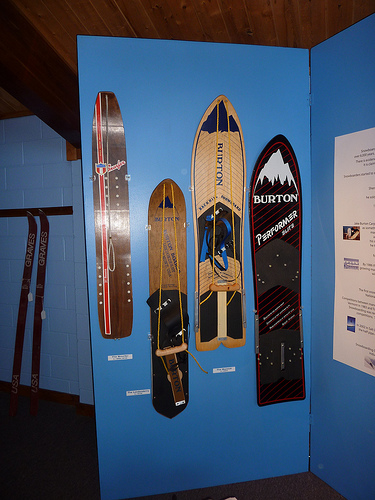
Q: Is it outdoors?
A: Yes, it is outdoors.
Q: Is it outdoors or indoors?
A: It is outdoors.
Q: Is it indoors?
A: No, it is outdoors.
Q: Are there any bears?
A: No, there are no bears.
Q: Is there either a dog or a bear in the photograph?
A: No, there are no bears or dogs.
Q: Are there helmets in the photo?
A: No, there are no helmets.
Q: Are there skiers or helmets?
A: No, there are no helmets or skiers.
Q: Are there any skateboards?
A: Yes, there is a skateboard.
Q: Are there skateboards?
A: Yes, there is a skateboard.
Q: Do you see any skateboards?
A: Yes, there is a skateboard.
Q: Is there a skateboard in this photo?
A: Yes, there is a skateboard.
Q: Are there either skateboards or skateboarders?
A: Yes, there is a skateboard.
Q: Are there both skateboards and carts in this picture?
A: No, there is a skateboard but no carts.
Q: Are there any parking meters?
A: No, there are no parking meters.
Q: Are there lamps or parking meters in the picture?
A: No, there are no parking meters or lamps.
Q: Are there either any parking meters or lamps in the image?
A: No, there are no parking meters or lamps.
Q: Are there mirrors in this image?
A: No, there are no mirrors.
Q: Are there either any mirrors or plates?
A: No, there are no mirrors or plates.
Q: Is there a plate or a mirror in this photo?
A: No, there are no mirrors or plates.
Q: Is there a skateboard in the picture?
A: Yes, there are skateboards.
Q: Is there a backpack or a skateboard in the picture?
A: Yes, there are skateboards.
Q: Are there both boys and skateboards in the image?
A: No, there are skateboards but no boys.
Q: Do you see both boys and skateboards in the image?
A: No, there are skateboards but no boys.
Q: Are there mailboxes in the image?
A: No, there are no mailboxes.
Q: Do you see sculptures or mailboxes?
A: No, there are no mailboxes or sculptures.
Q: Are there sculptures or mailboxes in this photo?
A: No, there are no mailboxes or sculptures.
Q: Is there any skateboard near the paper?
A: Yes, there are skateboards near the paper.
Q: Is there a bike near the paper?
A: No, there are skateboards near the paper.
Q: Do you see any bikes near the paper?
A: No, there are skateboards near the paper.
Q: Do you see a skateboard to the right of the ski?
A: Yes, there are skateboards to the right of the ski.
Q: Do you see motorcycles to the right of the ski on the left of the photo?
A: No, there are skateboards to the right of the ski.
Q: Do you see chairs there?
A: No, there are no chairs.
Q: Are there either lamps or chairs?
A: No, there are no chairs or lamps.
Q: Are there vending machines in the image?
A: No, there are no vending machines.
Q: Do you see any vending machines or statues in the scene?
A: No, there are no vending machines or statues.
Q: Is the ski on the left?
A: Yes, the ski is on the left of the image.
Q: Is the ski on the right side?
A: No, the ski is on the left of the image.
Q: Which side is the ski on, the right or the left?
A: The ski is on the left of the image.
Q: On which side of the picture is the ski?
A: The ski is on the left of the image.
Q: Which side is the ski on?
A: The ski is on the left of the image.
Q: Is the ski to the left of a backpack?
A: No, the ski is to the left of the skateboard.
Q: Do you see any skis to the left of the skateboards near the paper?
A: Yes, there is a ski to the left of the skateboards.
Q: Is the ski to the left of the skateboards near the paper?
A: Yes, the ski is to the left of the skateboards.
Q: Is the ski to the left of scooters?
A: No, the ski is to the left of the skateboards.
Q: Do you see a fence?
A: No, there are no fences.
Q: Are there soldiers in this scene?
A: No, there are no soldiers.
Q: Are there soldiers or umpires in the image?
A: No, there are no soldiers or umpires.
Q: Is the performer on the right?
A: Yes, the performer is on the right of the image.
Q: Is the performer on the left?
A: No, the performer is on the right of the image.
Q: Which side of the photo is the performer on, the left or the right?
A: The performer is on the right of the image.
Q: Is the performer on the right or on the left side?
A: The performer is on the right of the image.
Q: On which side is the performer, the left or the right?
A: The performer is on the right of the image.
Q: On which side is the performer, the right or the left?
A: The performer is on the right of the image.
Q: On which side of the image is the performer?
A: The performer is on the right of the image.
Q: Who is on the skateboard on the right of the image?
A: The performer is on the skateboard.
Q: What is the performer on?
A: The performer is on the skateboard.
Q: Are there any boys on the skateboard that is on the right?
A: No, there is a performer on the skateboard.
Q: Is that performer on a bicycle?
A: No, the performer is on the skateboard.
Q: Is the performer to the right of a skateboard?
A: Yes, the performer is to the right of a skateboard.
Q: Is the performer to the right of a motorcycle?
A: No, the performer is to the right of a skateboard.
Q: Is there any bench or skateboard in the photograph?
A: Yes, there is a skateboard.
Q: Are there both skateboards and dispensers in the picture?
A: No, there is a skateboard but no dispensers.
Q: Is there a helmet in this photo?
A: No, there are no helmets.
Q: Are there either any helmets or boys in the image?
A: No, there are no helmets or boys.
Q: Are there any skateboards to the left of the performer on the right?
A: Yes, there is a skateboard to the left of the performer.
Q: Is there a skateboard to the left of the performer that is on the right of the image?
A: Yes, there is a skateboard to the left of the performer.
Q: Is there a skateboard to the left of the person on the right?
A: Yes, there is a skateboard to the left of the performer.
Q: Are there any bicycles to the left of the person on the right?
A: No, there is a skateboard to the left of the performer.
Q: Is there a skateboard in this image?
A: Yes, there is a skateboard.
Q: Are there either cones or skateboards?
A: Yes, there is a skateboard.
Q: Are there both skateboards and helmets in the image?
A: No, there is a skateboard but no helmets.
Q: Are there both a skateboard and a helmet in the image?
A: No, there is a skateboard but no helmets.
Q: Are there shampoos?
A: No, there are no shampoos.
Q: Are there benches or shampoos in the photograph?
A: No, there are no shampoos or benches.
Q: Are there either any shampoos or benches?
A: No, there are no shampoos or benches.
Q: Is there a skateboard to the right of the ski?
A: Yes, there is a skateboard to the right of the ski.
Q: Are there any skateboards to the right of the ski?
A: Yes, there is a skateboard to the right of the ski.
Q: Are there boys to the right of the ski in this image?
A: No, there is a skateboard to the right of the ski.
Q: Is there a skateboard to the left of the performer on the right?
A: Yes, there is a skateboard to the left of the performer.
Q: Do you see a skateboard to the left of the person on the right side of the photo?
A: Yes, there is a skateboard to the left of the performer.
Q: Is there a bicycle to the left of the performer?
A: No, there is a skateboard to the left of the performer.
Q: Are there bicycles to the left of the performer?
A: No, there is a skateboard to the left of the performer.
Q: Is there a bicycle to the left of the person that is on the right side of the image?
A: No, there is a skateboard to the left of the performer.